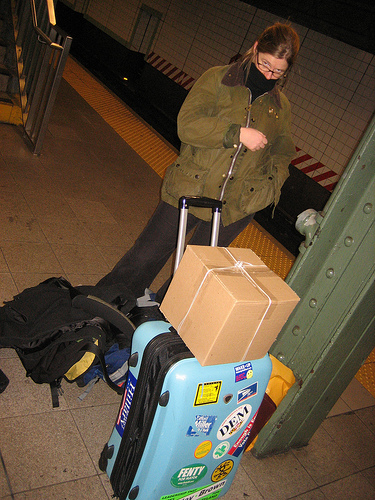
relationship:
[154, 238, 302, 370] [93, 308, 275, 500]
box on luggage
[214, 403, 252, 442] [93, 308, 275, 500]
stickers over luggage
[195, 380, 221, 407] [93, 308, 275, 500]
stickers over luggage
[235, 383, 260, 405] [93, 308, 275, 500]
stickers over luggage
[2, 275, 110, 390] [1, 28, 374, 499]
bags on ground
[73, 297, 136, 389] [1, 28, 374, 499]
bags on ground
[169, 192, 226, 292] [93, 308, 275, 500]
handle for luggage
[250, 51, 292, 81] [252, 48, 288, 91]
glasses on face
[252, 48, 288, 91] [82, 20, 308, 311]
face of woman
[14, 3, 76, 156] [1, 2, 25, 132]
handrail for stairs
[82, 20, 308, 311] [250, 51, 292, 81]
woman wearing glasses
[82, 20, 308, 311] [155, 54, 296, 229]
woman wearing jacket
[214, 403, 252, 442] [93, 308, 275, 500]
stickers on luggage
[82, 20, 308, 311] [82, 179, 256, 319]
woman wearing pants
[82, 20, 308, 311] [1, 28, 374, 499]
woman by ground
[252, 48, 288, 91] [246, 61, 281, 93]
face in collar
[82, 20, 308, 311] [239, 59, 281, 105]
woman wearing turtleneck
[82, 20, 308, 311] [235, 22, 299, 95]
woman with hair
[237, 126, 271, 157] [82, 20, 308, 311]
hand of woman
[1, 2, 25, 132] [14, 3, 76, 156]
stairs with handrail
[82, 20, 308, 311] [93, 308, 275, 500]
woman with luggage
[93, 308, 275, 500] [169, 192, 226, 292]
luggage with handle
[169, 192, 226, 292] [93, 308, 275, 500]
handle attached to luggage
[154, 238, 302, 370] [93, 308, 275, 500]
box on top of luggage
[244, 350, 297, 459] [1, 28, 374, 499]
envelope on ground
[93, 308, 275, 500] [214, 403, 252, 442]
luggage with stickers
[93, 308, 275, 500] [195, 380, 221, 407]
luggage with stickers